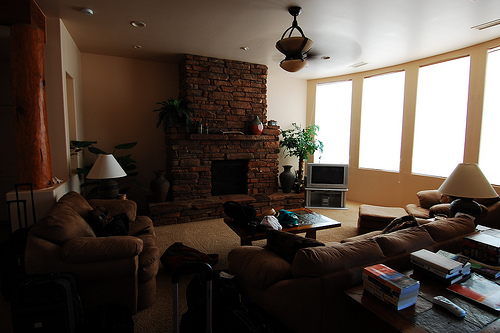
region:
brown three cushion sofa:
[224, 215, 476, 330]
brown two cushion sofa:
[24, 191, 158, 331]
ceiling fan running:
[231, 10, 364, 81]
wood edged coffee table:
[219, 203, 339, 243]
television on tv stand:
[306, 161, 348, 211]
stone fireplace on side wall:
[168, 129, 283, 194]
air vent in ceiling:
[470, 17, 499, 34]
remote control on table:
[430, 291, 466, 321]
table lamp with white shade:
[436, 162, 498, 233]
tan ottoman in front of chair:
[354, 202, 407, 230]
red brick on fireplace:
[210, 66, 223, 73]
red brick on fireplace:
[223, 66, 242, 75]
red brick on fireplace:
[186, 73, 211, 85]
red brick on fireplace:
[210, 79, 233, 87]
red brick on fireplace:
[227, 75, 249, 87]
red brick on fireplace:
[187, 102, 202, 109]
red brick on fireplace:
[200, 102, 223, 111]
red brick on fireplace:
[231, 109, 246, 116]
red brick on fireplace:
[177, 157, 202, 167]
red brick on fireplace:
[248, 159, 267, 167]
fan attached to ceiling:
[244, 19, 371, 105]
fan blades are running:
[249, 31, 366, 89]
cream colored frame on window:
[307, 70, 496, 235]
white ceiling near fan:
[288, 0, 445, 55]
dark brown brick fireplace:
[157, 59, 282, 211]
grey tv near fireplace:
[297, 163, 343, 209]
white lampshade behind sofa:
[86, 139, 123, 201]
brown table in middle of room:
[244, 175, 324, 240]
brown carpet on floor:
[160, 230, 235, 259]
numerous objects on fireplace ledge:
[168, 101, 283, 143]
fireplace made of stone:
[154, 52, 314, 226]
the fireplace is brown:
[139, 52, 316, 217]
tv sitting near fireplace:
[296, 152, 367, 217]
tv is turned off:
[297, 145, 362, 208]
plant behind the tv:
[277, 122, 322, 190]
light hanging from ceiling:
[262, 0, 332, 82]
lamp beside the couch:
[16, 140, 177, 325]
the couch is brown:
[17, 177, 172, 322]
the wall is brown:
[77, 42, 187, 207]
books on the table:
[351, 257, 429, 327]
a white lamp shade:
[437, 162, 499, 199]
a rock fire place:
[171, 55, 293, 209]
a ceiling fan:
[246, 12, 359, 72]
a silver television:
[306, 163, 350, 188]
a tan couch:
[43, 188, 163, 302]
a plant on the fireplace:
[156, 95, 193, 133]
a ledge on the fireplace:
[168, 118, 277, 142]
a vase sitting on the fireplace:
[281, 163, 294, 188]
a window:
[358, 74, 401, 172]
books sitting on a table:
[361, 261, 419, 308]